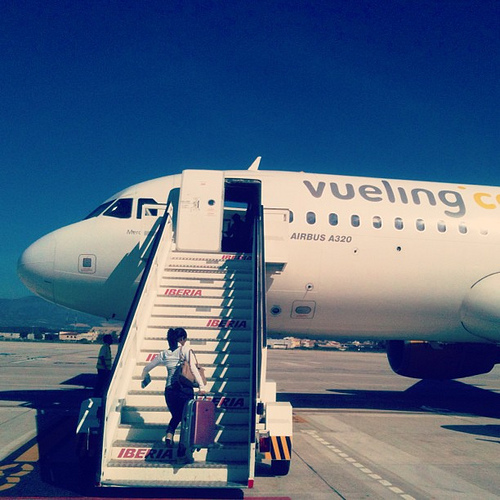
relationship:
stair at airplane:
[98, 204, 267, 488] [140, 165, 476, 275]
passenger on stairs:
[141, 327, 207, 457] [95, 207, 260, 487]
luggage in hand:
[180, 390, 219, 451] [192, 388, 209, 397]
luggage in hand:
[180, 390, 219, 451] [137, 370, 149, 382]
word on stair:
[162, 284, 207, 300] [157, 282, 254, 297]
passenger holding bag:
[141, 327, 207, 457] [174, 350, 209, 386]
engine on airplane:
[382, 332, 499, 381] [16, 155, 499, 379]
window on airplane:
[350, 213, 361, 228] [16, 155, 499, 379]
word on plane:
[304, 176, 498, 217] [13, 135, 499, 380]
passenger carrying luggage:
[141, 327, 207, 457] [180, 390, 216, 452]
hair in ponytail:
[167, 326, 189, 352] [164, 325, 176, 353]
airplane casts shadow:
[16, 155, 499, 379] [6, 366, 498, 443]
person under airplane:
[95, 333, 115, 391] [16, 155, 499, 379]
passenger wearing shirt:
[141, 327, 207, 457] [142, 342, 205, 391]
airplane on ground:
[16, 155, 499, 379] [2, 338, 497, 495]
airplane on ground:
[16, 155, 499, 379] [326, 387, 456, 487]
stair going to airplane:
[98, 204, 267, 488] [16, 155, 499, 379]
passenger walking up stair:
[141, 327, 207, 457] [98, 204, 267, 488]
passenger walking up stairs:
[141, 327, 207, 457] [97, 247, 257, 488]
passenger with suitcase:
[141, 327, 207, 457] [178, 393, 218, 452]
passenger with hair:
[141, 327, 207, 457] [164, 325, 189, 352]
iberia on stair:
[160, 285, 207, 300] [98, 204, 267, 488]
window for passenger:
[372, 216, 382, 229] [141, 327, 207, 462]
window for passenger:
[393, 216, 405, 231] [141, 327, 207, 462]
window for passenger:
[350, 213, 361, 228] [141, 327, 207, 462]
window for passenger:
[327, 212, 338, 227] [141, 327, 207, 462]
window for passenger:
[306, 212, 316, 224] [141, 327, 207, 462]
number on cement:
[0, 455, 32, 493] [1, 339, 496, 496]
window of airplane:
[137, 195, 159, 217] [16, 155, 499, 379]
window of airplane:
[114, 196, 133, 219] [16, 155, 499, 379]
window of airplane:
[88, 199, 115, 215] [16, 155, 499, 379]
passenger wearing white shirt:
[141, 327, 207, 457] [144, 350, 204, 386]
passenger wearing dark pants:
[141, 327, 207, 457] [161, 381, 201, 459]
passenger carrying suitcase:
[141, 327, 207, 457] [176, 386, 224, 458]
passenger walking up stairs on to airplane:
[141, 327, 207, 457] [16, 155, 499, 379]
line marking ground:
[300, 428, 418, 498] [270, 347, 498, 497]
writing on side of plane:
[309, 181, 464, 208] [72, 165, 497, 387]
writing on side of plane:
[463, 184, 496, 212] [4, 149, 494, 367]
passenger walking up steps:
[141, 327, 207, 457] [97, 243, 253, 478]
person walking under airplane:
[98, 333, 111, 387] [16, 155, 499, 379]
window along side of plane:
[305, 211, 316, 225] [11, 150, 498, 393]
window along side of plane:
[327, 209, 338, 227] [11, 150, 498, 393]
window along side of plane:
[391, 215, 406, 230] [11, 150, 498, 393]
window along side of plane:
[347, 211, 364, 228] [11, 150, 498, 393]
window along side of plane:
[432, 217, 448, 233] [11, 150, 498, 393]